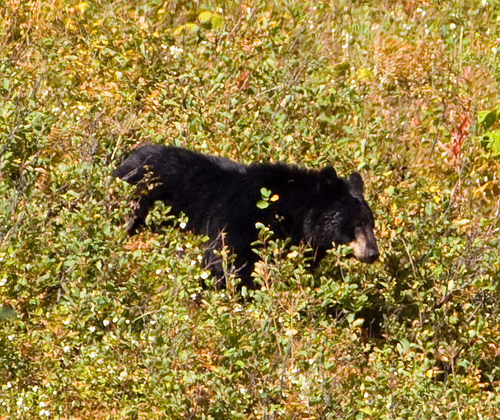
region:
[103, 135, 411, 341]
black bear in the shrubs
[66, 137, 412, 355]
big bear in the shrubs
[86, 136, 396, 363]
big black bear in the shrubs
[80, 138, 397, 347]
heavy bear in the shrubs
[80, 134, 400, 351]
dark bear in the shrubs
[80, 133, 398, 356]
strong bear in the shrubs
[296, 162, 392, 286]
head of a big bear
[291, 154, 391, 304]
head of a dark big bear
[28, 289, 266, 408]
patch of healthy shrubs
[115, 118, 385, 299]
black bear in the woods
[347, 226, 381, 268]
brown nose of bear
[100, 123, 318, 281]
large body of black bear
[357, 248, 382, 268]
small black nose of bear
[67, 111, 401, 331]
large black bear in bushes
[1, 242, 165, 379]
green leaves on bushes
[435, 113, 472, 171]
red leaves on bushes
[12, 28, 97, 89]
orange leaves on bushes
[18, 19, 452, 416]
large field of bushes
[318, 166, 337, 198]
the black ear of the bear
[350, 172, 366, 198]
the black ear of the bear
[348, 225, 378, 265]
the brown snout of the bear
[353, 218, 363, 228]
the brown eye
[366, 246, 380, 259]
the brown nose of the bear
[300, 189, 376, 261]
the dark brown head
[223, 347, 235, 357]
the green leaf of the plant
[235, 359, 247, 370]
the green leaf of the plant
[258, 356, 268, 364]
the green leaf of the plant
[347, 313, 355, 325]
the green leaf of the plant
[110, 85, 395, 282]
this is a dog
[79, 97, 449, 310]
the dog is black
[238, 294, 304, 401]
this is a plant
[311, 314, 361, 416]
this is a plant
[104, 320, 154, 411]
this is a plant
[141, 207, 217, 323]
this is a plant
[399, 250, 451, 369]
this is a plant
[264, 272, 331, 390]
this is a plant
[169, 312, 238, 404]
this is a plant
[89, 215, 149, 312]
this is a plant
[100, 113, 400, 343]
black bear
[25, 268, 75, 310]
green and brown leaves in bushes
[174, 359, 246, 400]
green and brown leaves in bushes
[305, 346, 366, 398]
green and brown leaves in bushes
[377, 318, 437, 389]
green and brown leaves in bushes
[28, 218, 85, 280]
green and brown leaves in bushes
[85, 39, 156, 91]
green and brown leaves in bushes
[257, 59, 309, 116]
green and brown leaves in bushes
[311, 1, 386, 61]
green and brown leaves in bushes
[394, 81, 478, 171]
green and brown leaves in bushes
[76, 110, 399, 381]
a bear in the grass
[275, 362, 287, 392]
green leaves on the branch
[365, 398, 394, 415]
green leaves on the branch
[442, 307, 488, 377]
green leaves on the branch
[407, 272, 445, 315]
green leaves on the branch